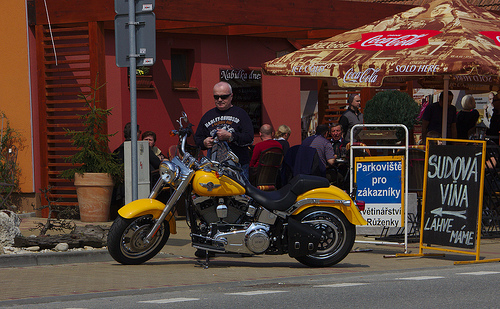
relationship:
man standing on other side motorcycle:
[195, 78, 256, 199] [108, 115, 366, 278]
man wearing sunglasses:
[190, 82, 253, 258] [209, 88, 236, 100]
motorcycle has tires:
[108, 110, 368, 268] [289, 206, 357, 266]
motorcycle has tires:
[108, 110, 368, 268] [104, 210, 177, 262]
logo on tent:
[340, 63, 384, 84] [262, 0, 499, 89]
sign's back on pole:
[113, 1, 157, 68] [124, 2, 141, 199]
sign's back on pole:
[122, 137, 152, 198] [124, 2, 141, 199]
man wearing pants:
[190, 82, 253, 258] [197, 143, 246, 185]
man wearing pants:
[190, 82, 253, 258] [188, 149, 253, 265]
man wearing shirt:
[190, 82, 253, 258] [195, 105, 255, 160]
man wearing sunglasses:
[190, 82, 253, 258] [193, 87, 242, 108]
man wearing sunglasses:
[190, 82, 253, 258] [210, 91, 231, 101]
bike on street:
[110, 114, 360, 272] [70, 259, 466, 306]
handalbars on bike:
[172, 115, 252, 168] [110, 114, 360, 272]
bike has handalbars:
[110, 114, 360, 272] [172, 115, 252, 168]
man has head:
[190, 82, 253, 258] [211, 82, 233, 109]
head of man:
[211, 82, 233, 109] [190, 82, 253, 258]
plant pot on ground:
[73, 171, 115, 223] [42, 219, 105, 239]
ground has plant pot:
[42, 219, 105, 239] [73, 171, 115, 223]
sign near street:
[392, 132, 498, 267] [200, 269, 484, 306]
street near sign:
[200, 269, 484, 306] [392, 132, 498, 267]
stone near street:
[52, 236, 77, 253] [38, 267, 478, 306]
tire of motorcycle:
[106, 208, 168, 266] [108, 115, 366, 278]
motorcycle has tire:
[108, 115, 366, 278] [106, 208, 168, 266]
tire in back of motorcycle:
[289, 202, 356, 268] [108, 115, 366, 278]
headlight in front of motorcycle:
[152, 159, 177, 190] [108, 115, 366, 278]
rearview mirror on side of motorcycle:
[214, 147, 241, 164] [78, 117, 365, 262]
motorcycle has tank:
[108, 110, 368, 268] [193, 167, 243, 197]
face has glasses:
[211, 82, 233, 114] [213, 92, 233, 100]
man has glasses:
[190, 82, 253, 258] [213, 92, 233, 100]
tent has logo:
[262, 3, 498, 89] [359, 34, 429, 58]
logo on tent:
[359, 34, 429, 58] [262, 3, 498, 89]